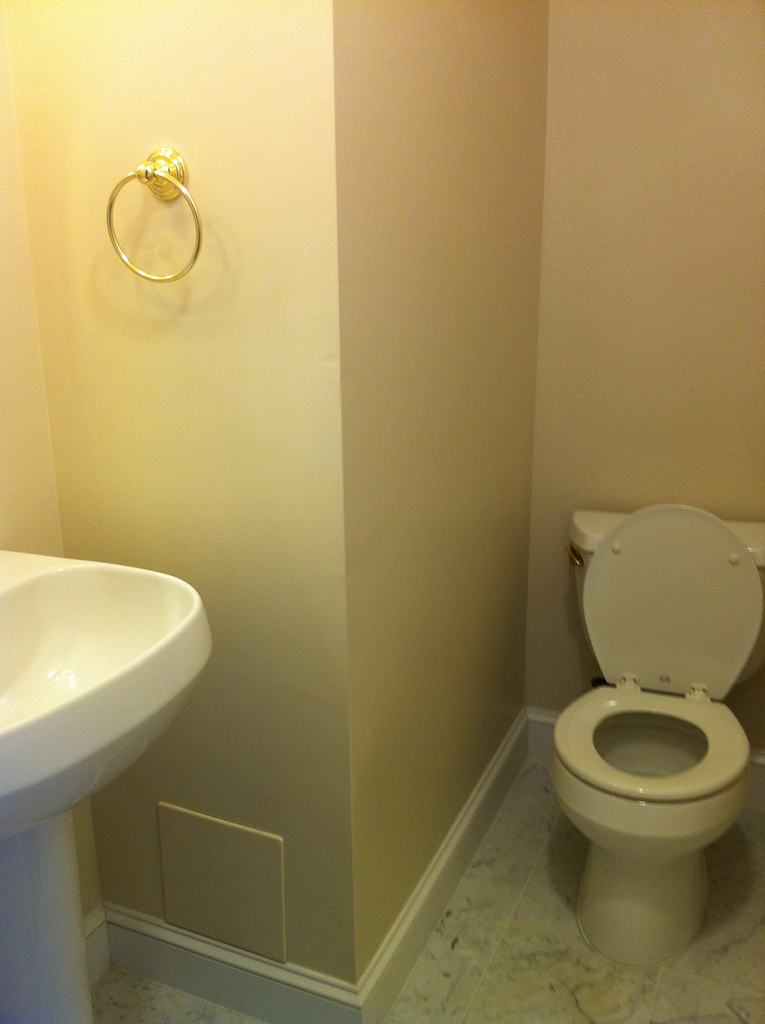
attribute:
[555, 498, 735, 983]
toilet — white, new, clean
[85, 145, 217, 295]
hook — metal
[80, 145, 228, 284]
hook — silver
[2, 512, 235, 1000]
sink — clean, new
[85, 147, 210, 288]
towel holder — gold, round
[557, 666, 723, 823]
toilet seat — white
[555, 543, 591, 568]
toilet flusher — gold 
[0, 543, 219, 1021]
white sink — tall , white 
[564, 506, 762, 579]
tank lid — white 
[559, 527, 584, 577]
gold flusher — gold 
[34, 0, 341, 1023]
beige wall — Beige 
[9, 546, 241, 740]
sink top — white 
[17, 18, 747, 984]
bathroom — white , grey 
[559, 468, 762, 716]
toilet lid — white 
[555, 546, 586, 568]
fush lever — silver  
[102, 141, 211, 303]
gold holder — gold 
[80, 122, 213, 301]
towel holder — gold 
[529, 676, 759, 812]
seat — white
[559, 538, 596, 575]
handle — silver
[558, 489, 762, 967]
toilet seat — open 